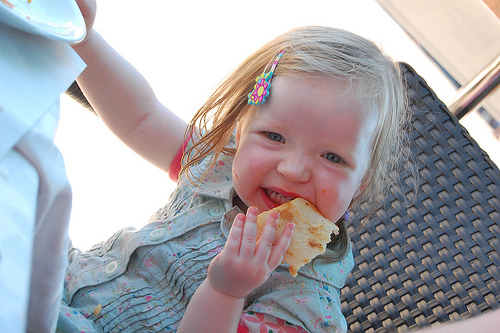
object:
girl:
[53, 0, 415, 333]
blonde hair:
[181, 24, 409, 207]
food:
[255, 198, 339, 277]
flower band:
[244, 49, 284, 106]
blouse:
[59, 134, 352, 331]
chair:
[341, 61, 497, 328]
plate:
[0, 0, 87, 43]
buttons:
[148, 226, 168, 240]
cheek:
[316, 175, 349, 209]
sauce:
[321, 189, 326, 195]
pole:
[448, 54, 499, 119]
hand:
[209, 206, 296, 300]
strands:
[167, 36, 276, 165]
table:
[3, 30, 72, 331]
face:
[231, 68, 379, 225]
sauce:
[230, 170, 241, 177]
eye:
[255, 127, 288, 146]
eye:
[319, 151, 348, 168]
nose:
[276, 152, 311, 184]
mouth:
[261, 186, 312, 209]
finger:
[227, 212, 247, 254]